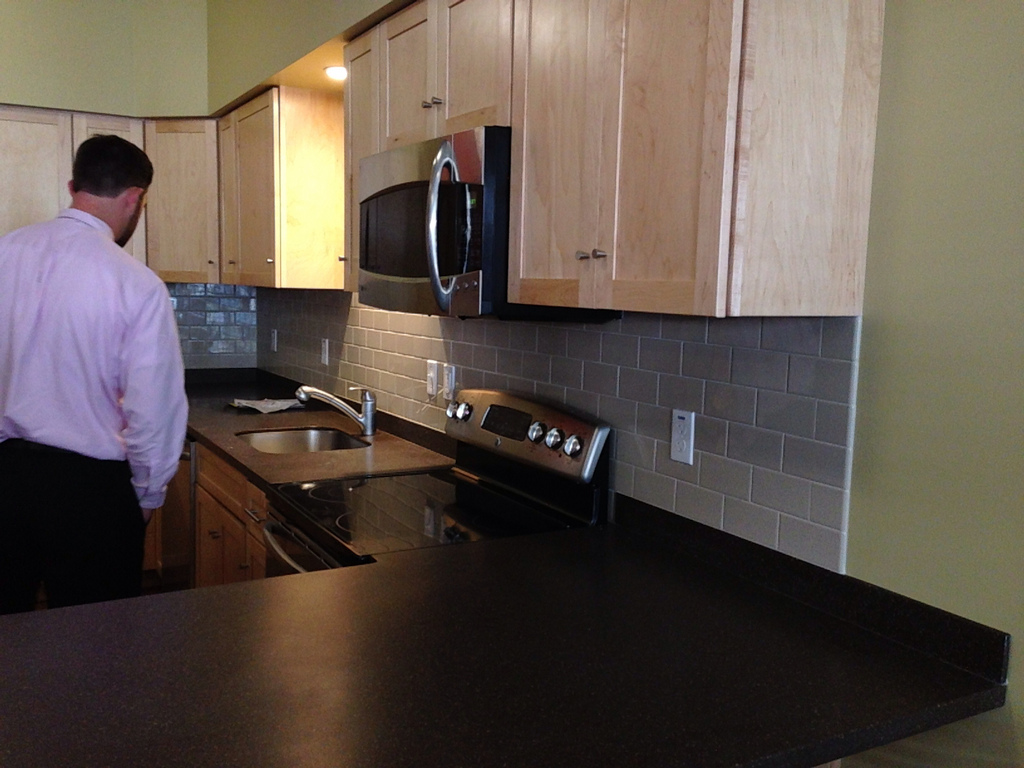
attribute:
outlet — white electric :
[662, 402, 706, 470]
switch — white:
[657, 394, 709, 474]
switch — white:
[439, 364, 457, 403]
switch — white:
[415, 348, 448, 403]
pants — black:
[0, 417, 191, 623]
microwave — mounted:
[337, 127, 493, 328]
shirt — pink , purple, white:
[6, 198, 203, 507]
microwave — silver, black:
[338, 117, 509, 323]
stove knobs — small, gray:
[516, 407, 571, 462]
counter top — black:
[5, 359, 978, 746]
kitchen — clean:
[11, 16, 994, 734]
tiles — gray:
[262, 286, 865, 567]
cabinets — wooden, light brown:
[11, 9, 846, 321]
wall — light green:
[843, 14, 993, 741]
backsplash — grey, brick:
[176, 288, 868, 569]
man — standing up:
[13, 119, 199, 586]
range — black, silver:
[271, 368, 607, 572]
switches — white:
[415, 351, 457, 406]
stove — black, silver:
[255, 364, 612, 568]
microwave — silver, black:
[344, 104, 504, 329]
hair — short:
[63, 126, 157, 194]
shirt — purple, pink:
[22, 202, 195, 518]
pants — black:
[14, 430, 149, 588]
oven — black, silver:
[264, 368, 617, 561]